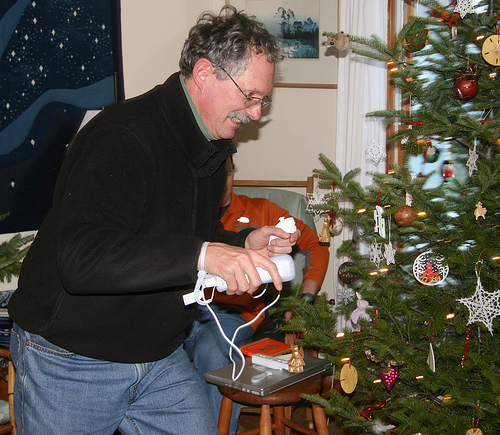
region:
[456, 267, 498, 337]
a white snowflake ornament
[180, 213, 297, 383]
a wii remote being used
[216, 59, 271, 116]
a pair of eyeglasses being worn by a man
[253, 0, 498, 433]
a christmas tree decorated with many ornaments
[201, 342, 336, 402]
a grey coffee table book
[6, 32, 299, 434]
an adult playing wii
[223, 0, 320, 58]
a painting hanging on the wall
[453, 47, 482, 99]
a red apple ornament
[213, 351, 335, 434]
a wooden stool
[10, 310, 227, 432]
a pair of jeans worn by man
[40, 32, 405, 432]
man decorating a Christmas tree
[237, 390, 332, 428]
the stool is wooden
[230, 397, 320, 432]
the stool is brown in color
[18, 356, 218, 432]
the jeans is light blue in color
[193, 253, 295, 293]
the hand machine is white in color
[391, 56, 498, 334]
the tree has green leafs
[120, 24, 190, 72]
the wall is white in color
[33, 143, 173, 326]
the sweater is black in color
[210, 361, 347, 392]
the laptop is silver in color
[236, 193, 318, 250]
the sweater is orange in color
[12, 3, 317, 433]
man playing a video game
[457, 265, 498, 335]
white snowflake ornament on christmas tree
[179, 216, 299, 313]
white video game controllers man is holding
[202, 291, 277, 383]
white cord of game controllers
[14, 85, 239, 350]
black sweater man is wearing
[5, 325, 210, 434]
blue jeans man is wearing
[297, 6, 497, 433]
christmas tree with ornaments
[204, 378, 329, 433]
wood stool beside christmas tree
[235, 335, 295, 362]
red book sitting on wood stool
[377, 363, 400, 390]
purple ornament on christmas tree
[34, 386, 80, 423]
jeans on the man.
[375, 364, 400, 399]
purple ornament on tree.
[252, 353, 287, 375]
controller on the stool.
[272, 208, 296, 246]
controller in man's hand.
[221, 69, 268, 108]
glasses on man's face.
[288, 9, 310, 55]
painting on the wall.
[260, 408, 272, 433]
stool made of wood.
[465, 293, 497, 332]
white decoration on tree.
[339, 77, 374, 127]
curtain near the window.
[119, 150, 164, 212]
black top on man.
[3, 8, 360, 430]
man in front of tree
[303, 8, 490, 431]
holiday tree with ornaments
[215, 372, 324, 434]
stool in front of tree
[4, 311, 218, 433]
pants on man near tree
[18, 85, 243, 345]
sweater on the man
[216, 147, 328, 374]
person in back of man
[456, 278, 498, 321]
star on holiday tree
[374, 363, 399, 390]
ornament on the tree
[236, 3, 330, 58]
image on the wall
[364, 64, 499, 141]
branches on the tree